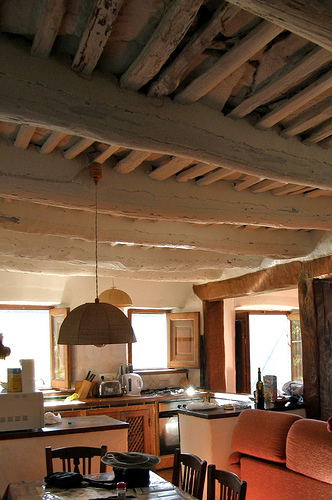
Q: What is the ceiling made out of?
A: Logs.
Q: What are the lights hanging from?
A: The ceiling.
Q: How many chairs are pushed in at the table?
A: Three.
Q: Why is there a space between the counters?
A: It is an entrance.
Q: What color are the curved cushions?
A: Orange.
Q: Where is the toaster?
A: On a countertop.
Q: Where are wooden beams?
A: On the ceiling.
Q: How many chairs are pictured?
A: Three.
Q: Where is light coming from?
A: Windows.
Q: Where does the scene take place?
A: In a house.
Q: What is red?
A: Couch.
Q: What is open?
A: Shutters.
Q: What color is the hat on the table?
A: Black.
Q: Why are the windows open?
A: To get some air.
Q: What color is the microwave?
A: White.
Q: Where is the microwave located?
A: On the countertop.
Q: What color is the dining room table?
A: Brown.